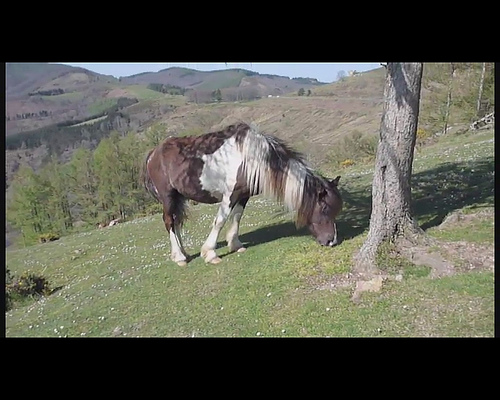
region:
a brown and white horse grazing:
[129, 124, 343, 275]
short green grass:
[139, 277, 309, 334]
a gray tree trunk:
[372, 94, 440, 251]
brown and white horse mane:
[243, 134, 317, 214]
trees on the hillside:
[7, 156, 144, 217]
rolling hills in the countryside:
[14, 72, 320, 127]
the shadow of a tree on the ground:
[414, 165, 498, 214]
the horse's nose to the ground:
[314, 225, 346, 245]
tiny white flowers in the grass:
[44, 275, 121, 330]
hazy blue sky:
[107, 65, 133, 74]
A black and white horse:
[133, 117, 353, 264]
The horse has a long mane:
[238, 125, 348, 250]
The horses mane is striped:
[241, 124, 323, 227]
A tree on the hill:
[301, 74, 463, 291]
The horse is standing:
[123, 113, 367, 288]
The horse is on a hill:
[118, 116, 397, 288]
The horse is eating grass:
[136, 106, 362, 277]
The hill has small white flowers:
[11, 152, 464, 318]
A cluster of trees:
[26, 120, 238, 230]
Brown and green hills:
[41, 67, 377, 174]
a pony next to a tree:
[131, 111, 350, 272]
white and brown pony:
[116, 116, 345, 275]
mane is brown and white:
[228, 114, 323, 234]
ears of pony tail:
[311, 170, 348, 205]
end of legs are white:
[156, 227, 257, 273]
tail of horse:
[134, 143, 188, 235]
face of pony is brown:
[306, 176, 348, 251]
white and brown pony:
[130, 116, 262, 213]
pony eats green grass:
[131, 113, 353, 278]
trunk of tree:
[351, 60, 441, 267]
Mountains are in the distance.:
[4, 60, 346, 112]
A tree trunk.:
[353, 51, 435, 285]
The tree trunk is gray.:
[356, 57, 428, 269]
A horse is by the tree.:
[138, 109, 425, 287]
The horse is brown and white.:
[119, 118, 356, 275]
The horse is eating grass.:
[126, 115, 348, 279]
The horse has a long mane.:
[139, 117, 344, 275]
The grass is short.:
[148, 280, 275, 341]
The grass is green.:
[158, 278, 303, 334]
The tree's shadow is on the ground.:
[357, 140, 496, 240]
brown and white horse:
[120, 124, 335, 263]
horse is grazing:
[103, 126, 400, 300]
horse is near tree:
[153, 90, 439, 275]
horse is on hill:
[67, 226, 473, 338]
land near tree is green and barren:
[71, 161, 464, 326]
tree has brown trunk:
[370, 64, 434, 281]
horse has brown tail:
[128, 151, 178, 217]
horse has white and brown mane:
[223, 124, 366, 226]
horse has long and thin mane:
[237, 123, 332, 219]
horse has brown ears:
[307, 178, 347, 203]